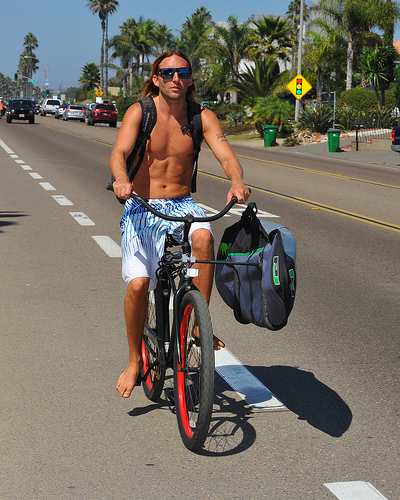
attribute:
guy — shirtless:
[109, 49, 250, 399]